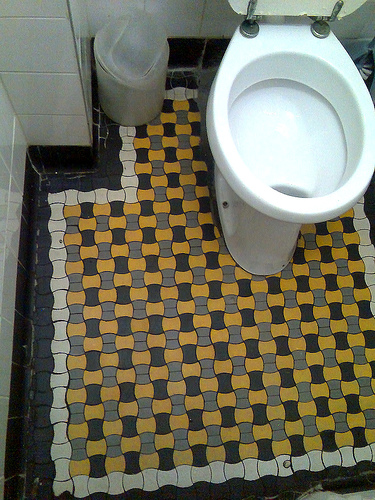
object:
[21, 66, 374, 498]
floor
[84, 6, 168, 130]
trash can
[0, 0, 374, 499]
toilet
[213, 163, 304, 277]
base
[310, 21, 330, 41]
metal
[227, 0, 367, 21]
lid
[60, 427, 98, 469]
tiles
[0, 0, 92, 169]
wall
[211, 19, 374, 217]
seat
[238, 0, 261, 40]
hinges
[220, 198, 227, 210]
bolt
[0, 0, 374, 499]
bathroom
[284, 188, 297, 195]
water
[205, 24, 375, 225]
bowl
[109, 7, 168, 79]
lid